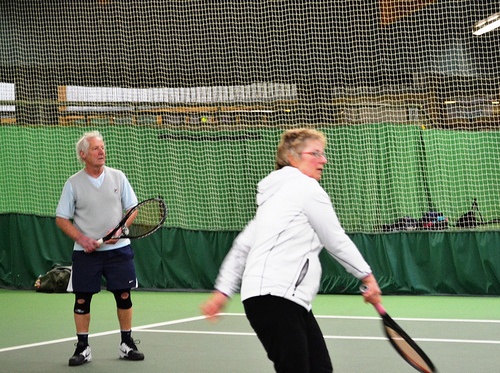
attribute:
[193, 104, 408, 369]
woman — playing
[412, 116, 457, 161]
wall — black 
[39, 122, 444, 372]
people — elderly, playing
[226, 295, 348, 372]
pants — black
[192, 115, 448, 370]
woman — playing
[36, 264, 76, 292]
dufflebag — duffle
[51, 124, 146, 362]
man — gray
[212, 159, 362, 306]
jacket — white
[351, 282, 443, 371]
racket — black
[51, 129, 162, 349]
man — black 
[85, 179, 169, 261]
racket — tennis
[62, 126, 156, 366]
man — playing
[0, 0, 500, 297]
green net — green 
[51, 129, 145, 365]
male — playing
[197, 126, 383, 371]
female — playing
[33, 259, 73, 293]
bag — duffle, green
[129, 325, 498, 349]
white line — long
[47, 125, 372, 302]
two people — old, playing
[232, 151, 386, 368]
woman — black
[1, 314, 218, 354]
line — white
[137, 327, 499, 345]
line — white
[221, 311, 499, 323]
line — white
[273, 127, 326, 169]
hair — gray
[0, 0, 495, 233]
net — white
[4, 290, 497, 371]
tennis court — green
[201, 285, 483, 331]
line — white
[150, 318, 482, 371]
line — white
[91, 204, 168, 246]
racket — black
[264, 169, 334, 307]
hoodie — white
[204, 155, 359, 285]
jacket — white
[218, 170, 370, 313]
jacket — white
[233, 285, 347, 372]
pants — black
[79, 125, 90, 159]
hair — gray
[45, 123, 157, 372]
man — blue 